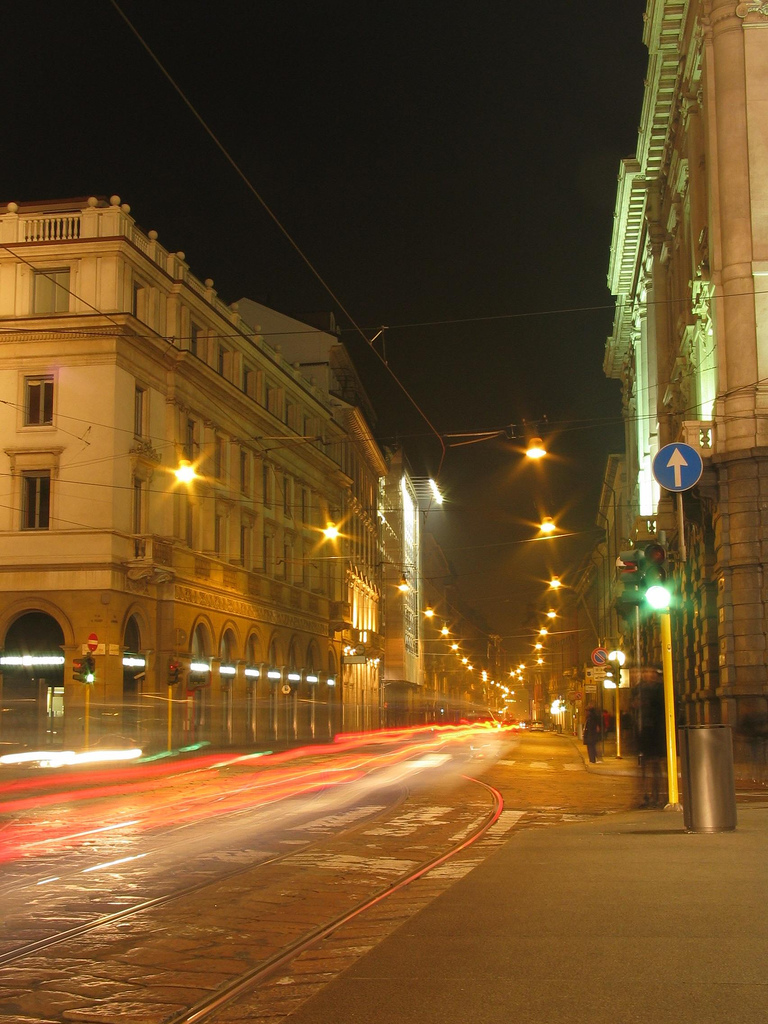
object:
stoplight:
[72, 649, 96, 751]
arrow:
[666, 447, 688, 486]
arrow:
[168, 438, 569, 704]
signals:
[644, 540, 672, 611]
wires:
[0, 285, 768, 340]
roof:
[593, 0, 689, 384]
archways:
[0, 595, 66, 746]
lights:
[425, 477, 455, 513]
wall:
[383, 444, 403, 680]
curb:
[584, 761, 603, 770]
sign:
[652, 440, 704, 494]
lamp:
[640, 528, 683, 812]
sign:
[87, 633, 99, 652]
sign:
[591, 646, 610, 666]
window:
[19, 463, 52, 530]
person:
[582, 704, 599, 762]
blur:
[1, 737, 520, 868]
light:
[0, 744, 144, 771]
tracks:
[0, 759, 508, 1022]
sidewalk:
[278, 800, 765, 1021]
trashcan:
[676, 723, 737, 832]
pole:
[658, 529, 683, 813]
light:
[640, 575, 678, 613]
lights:
[515, 435, 550, 465]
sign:
[174, 583, 330, 640]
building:
[0, 194, 386, 753]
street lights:
[540, 510, 557, 532]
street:
[0, 720, 768, 1021]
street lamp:
[165, 654, 183, 755]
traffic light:
[620, 525, 689, 805]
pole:
[85, 652, 90, 748]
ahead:
[0, 588, 753, 1020]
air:
[0, 2, 767, 1020]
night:
[0, 0, 768, 1021]